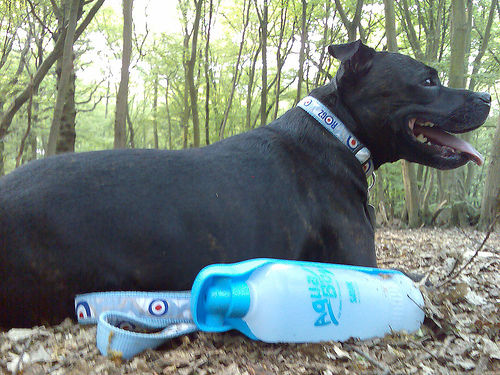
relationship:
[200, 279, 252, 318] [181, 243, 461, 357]
top of a bottle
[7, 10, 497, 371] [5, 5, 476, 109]
photo taken in woodland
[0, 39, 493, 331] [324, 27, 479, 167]
dog has head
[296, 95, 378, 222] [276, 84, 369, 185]
collar on neck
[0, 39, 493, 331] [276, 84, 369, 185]
dog has neck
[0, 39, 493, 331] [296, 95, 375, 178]
dog wearing collar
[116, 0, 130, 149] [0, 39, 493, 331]
tree behind dog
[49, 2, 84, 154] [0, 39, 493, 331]
tree behind dog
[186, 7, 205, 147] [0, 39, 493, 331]
tree behind dog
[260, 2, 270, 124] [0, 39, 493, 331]
tree behind dog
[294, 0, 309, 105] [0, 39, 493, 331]
tree behind dog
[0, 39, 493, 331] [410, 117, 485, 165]
dog has tongue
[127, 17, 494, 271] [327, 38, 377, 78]
dog has ear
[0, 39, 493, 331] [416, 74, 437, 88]
dog has eye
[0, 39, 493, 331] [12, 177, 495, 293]
dog on foreground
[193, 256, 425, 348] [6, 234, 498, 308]
bottle on foreground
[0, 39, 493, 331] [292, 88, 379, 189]
dog wears collar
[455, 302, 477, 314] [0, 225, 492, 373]
leaf on ground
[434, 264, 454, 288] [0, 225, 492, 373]
leaf on ground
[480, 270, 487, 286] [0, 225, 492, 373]
leaf on ground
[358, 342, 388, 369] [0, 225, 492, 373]
leaf on ground